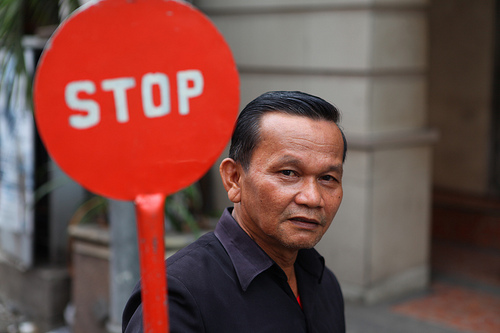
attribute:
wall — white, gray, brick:
[298, 12, 494, 296]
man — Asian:
[124, 85, 345, 331]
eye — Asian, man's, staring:
[315, 173, 340, 186]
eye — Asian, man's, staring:
[282, 162, 301, 184]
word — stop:
[61, 68, 203, 128]